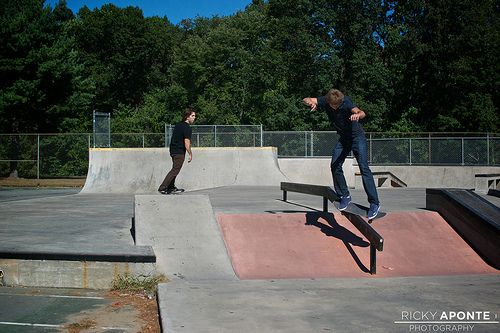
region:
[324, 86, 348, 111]
the head of a man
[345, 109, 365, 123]
the hand of a man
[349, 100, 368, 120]
the arm of a man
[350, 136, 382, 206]
the leg of a man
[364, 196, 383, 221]
a blue and white shoe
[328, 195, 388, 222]
a black skateboard under the man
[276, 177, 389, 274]
a black railing under the skateboard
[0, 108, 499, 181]
a chain link fence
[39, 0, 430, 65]
a clear blue sky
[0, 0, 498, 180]
green trees behind the fence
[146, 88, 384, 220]
Boys skateboarding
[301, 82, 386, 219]
Boy is on skateboard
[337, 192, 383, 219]
Boy is wearing shoes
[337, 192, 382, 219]
Boy is wearing blue shoes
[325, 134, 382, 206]
Boy is wearing pants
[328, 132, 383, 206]
Boy is wearing jeans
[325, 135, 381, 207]
Boy is wearing blue jeans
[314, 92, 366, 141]
Boy is wearing a shirt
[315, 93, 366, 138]
Boy is wearing a blue shirt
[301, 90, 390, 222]
Boy is doing a trick on a skateboard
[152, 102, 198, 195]
Boy is skateboarding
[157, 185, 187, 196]
Boy is wearing shoes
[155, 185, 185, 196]
Boy is wearing black shoes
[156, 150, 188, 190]
Boy is wearing pants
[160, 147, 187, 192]
Boy is wearing brown pants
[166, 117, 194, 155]
Boy is wearing a shirt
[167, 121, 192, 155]
Boy is wearing a black shirt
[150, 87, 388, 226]
Boys are skateboarding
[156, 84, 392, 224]
Boys are skateboarding at a skate park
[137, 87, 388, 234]
Two boys are skateboarding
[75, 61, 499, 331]
picture taken outdoors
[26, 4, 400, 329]
picture taken during the day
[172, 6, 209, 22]
the sky is void of clouds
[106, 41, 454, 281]
two boys in a skate park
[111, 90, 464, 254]
both boys are skate boarding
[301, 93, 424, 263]
a boy is doing a trick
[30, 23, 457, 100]
very tall thick trees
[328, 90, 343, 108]
the boy has short hair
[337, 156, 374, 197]
the boy wears jeans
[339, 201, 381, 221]
the boy has blue shoes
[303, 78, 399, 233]
man skateboarding on a railing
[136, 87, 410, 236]
two men skateboarding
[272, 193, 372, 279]
shadow on the ground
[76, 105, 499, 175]
silver chain link fence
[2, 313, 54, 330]
white line on the ground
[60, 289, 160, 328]
pile of dirt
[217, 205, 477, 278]
faded red paint on the incline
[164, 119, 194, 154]
black short sleeve shirt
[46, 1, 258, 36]
bright blue sky visible over the tree tops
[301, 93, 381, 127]
both arms are in the air